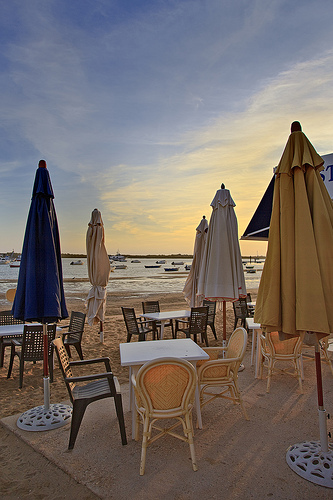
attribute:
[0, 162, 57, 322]
umbrella — closed, yellow, white, folded, blue, beige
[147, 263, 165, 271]
boat — small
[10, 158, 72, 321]
umbrella — blue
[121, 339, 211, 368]
table — white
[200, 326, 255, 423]
chairs — dark, tan, brown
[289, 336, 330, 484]
stand — metal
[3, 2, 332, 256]
sky — blue